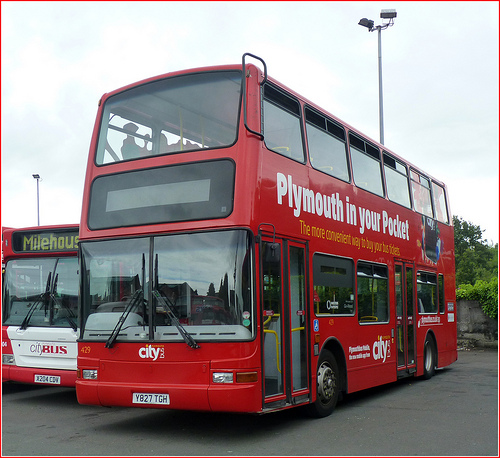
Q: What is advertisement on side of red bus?
A: Plymouth in your pocket.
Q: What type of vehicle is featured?
A: Double decker bus.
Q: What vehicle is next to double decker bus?
A: Regular bus.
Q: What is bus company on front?
A: City bus.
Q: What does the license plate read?
A: Y827TGH.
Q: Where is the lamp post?
A: Behind the buses.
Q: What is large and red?
A: Bus.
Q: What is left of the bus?
A: Bus.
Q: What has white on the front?
A: Bus on left.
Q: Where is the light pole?
A: Behind bus.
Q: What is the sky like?
A: Cloudy.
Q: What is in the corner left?
A: Smaller bus.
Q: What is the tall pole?
A: Light post.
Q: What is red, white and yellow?
A: Double deck bus.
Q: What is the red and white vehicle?
A: A bus.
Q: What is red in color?
A: The bus.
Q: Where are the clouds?
A: In the sky.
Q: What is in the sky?
A: Clouds.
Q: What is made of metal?
A: Bus.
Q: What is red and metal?
A: Bus.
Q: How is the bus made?
A: Double decker.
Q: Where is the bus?
A: On the road.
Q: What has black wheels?
A: Bus.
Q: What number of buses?
A: Two.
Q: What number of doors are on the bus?
A: Three.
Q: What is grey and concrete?
A: Road.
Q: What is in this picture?
A: Buses.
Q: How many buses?
A: Two.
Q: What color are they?
A: Red.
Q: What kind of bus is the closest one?
A: A double-decker bus.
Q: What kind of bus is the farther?
A: Single-decker.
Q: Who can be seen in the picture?
A: No one.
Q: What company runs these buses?
A: City Bus.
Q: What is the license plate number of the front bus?
A: YB27 TGH.